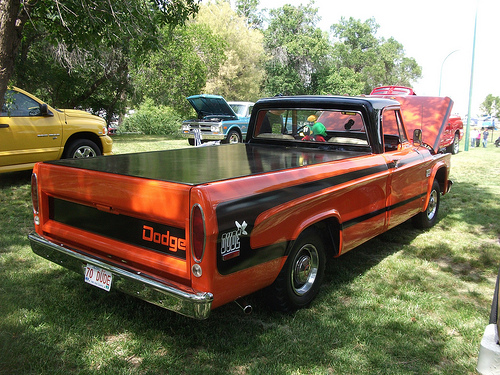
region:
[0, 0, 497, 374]
a truck show event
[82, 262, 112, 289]
a registered license plate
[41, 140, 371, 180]
a black truck bed cover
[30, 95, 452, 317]
a red and black doge pickup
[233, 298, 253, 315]
the chrome exhaust pipe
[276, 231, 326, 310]
the rear wheel and tire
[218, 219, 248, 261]
the trucks name DUDE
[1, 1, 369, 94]
large trees in the background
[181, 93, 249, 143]
a blue and white dodge truck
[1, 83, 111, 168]
a gold dodge pick up truck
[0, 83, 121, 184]
yellow vehicle parked on the grass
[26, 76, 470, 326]
black and red pickup truck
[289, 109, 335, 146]
man in a green shirt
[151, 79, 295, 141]
pickup truck with an open hood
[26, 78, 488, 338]
Vintage dodge pickup truck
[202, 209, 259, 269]
the word "Dude" written on the truck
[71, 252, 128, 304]
license plate reads "70 DUDE"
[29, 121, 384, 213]
truck bed has a black cover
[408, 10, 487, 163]
two light posts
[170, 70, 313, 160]
blue vintage pickup truck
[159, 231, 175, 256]
word dodge is written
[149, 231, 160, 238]
word dodge is written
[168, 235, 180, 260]
word dodge is written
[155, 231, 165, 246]
word dodge is written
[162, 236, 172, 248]
word dodge is written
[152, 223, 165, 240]
word dodge is written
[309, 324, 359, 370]
the grass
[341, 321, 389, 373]
the grass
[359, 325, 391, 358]
the grass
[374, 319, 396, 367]
the grass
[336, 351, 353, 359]
the grass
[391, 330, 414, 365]
the grass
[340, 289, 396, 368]
the grass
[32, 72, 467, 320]
The truck is orange.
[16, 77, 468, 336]
The truck is a Dodge.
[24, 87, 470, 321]
Truck has black highlights.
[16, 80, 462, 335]
Truck has chrome bumper.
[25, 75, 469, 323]
Hood of truck is open.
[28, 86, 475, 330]
The truck is an older model.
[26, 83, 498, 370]
The truck is parked.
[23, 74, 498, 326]
Truck sitting on grass.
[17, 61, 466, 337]
Truck has license plate.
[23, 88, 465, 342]
Tip of exhaust pipe is chrome.